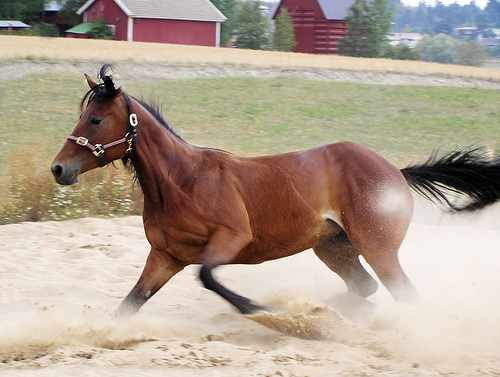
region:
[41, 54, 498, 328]
brown horse running in the sand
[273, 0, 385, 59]
red barn in the distance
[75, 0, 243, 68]
second red barn in the distance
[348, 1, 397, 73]
green trees in the distance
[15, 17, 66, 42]
bush by the red barn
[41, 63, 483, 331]
red horse running in sand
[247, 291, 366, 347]
sand stirred up by horse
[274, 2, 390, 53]
red barn in background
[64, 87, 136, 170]
red and black bridal on horse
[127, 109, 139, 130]
silver buckle on horse bridal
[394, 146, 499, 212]
black hairy tail of horse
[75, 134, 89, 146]
silver buckle on front of bridal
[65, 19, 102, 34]
green awning on red shed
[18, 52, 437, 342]
the horse is brown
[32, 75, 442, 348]
the horse is brown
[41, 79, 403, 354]
the horse is brown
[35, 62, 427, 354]
the horse is brown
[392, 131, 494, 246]
horse's tail is black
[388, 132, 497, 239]
horse's tail is black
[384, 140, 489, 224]
horse's tail is black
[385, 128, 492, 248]
horse's tail is black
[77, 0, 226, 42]
red barn with slanted roof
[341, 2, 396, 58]
green leaves on tree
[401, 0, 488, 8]
light of daytime sky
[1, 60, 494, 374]
horse running in sand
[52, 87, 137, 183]
bridle on horse head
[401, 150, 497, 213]
tail on back of horse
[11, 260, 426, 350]
legs kicking up sand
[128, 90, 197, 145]
mane on neck of horse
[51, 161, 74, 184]
nostril on horse nose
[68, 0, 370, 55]
two red buildings behind hill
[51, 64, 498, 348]
The horse is running.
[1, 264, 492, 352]
The dust is below the horse.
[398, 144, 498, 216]
The horse has a black tail.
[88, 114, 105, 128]
The color of the horses eye is black.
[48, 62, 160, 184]
The horse is wearing a bridle.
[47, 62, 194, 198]
The horses mane is black.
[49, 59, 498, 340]
The horse is brown and black.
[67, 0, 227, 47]
The barn in the background is red.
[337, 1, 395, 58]
The tree in the background is green.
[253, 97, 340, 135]
The grass in the background is green.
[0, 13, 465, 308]
the horse is running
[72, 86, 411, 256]
this is a horse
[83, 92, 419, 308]
the horse is in motion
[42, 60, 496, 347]
a horse running through sand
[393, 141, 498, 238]
a black tail on the horse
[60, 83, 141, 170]
a red-and-black halter on a horse's head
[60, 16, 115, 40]
A very small red building attachment with a green roof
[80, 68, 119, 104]
two horses ears that are perked up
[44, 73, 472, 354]
This horse is a brown color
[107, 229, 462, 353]
The horse is losing balance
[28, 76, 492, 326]
The horse is galloping swiftly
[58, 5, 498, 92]
There are red barns in the background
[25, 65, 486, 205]
There is shrubery behind the horse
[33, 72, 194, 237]
The horse is focused on something in the distance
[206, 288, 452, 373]
Water is being kicked up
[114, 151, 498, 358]
The horse is dirty with mud